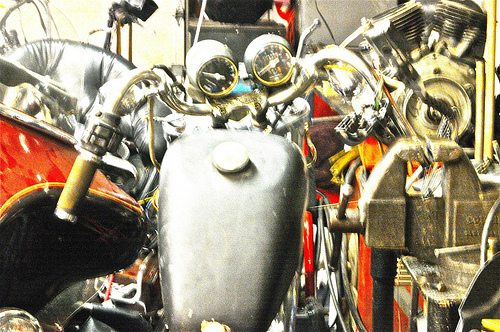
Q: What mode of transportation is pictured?
A: Motorcycle.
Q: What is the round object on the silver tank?
A: Gas tank.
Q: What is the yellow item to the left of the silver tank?
A: Handlebar.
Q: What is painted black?
A: Gas tank.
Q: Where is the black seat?
A: Behind the motorcycle.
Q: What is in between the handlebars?
A: Gauges.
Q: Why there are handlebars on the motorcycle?
A: To direct the motorcycle.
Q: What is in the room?
A: Motorcycle parts.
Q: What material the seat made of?
A: Leather.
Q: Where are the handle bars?
A: Attached to the motorcycle.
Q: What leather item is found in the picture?
A: Seat.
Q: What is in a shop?
A: A bike.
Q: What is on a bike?
A: A fuel tank.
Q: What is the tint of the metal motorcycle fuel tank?
A: Black.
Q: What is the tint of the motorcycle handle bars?
A: Chrome.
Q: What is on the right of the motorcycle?
A: Engine block.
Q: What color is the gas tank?
A: Black.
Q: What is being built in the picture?
A: Motorcycle.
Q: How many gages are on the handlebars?
A: Two.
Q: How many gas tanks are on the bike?
A: One.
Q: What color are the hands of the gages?
A: White.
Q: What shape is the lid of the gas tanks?
A: Circle.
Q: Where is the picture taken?
A: A garage.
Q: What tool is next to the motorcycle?
A: A vice.